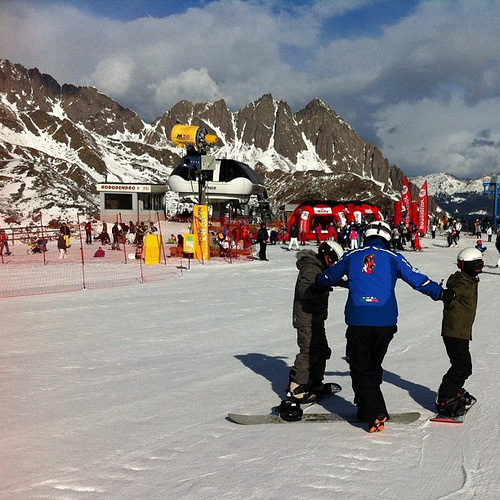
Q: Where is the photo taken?
A: Ski slope.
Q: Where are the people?
A: In the snow.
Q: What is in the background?
A: Mountains.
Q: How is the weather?
A: Cloudy.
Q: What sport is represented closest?
A: Snowboarding.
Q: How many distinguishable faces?
A: Zero.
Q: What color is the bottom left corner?
A: White.